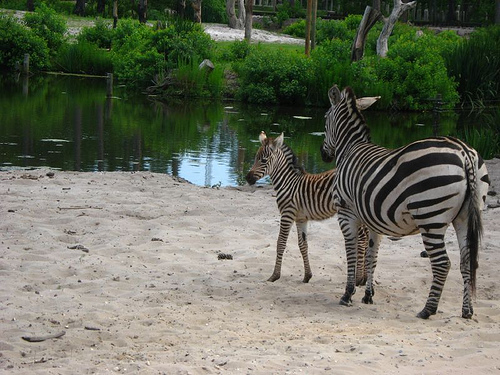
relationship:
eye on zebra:
[321, 115, 330, 124] [319, 82, 490, 322]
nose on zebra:
[318, 146, 329, 159] [319, 82, 490, 322]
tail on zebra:
[463, 152, 483, 298] [319, 82, 490, 322]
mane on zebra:
[340, 87, 374, 150] [319, 82, 490, 322]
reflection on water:
[177, 124, 252, 193] [4, 67, 499, 186]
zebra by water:
[319, 82, 490, 322] [4, 67, 499, 186]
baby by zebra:
[241, 125, 380, 290] [319, 82, 490, 322]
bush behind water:
[111, 16, 179, 89] [4, 67, 499, 186]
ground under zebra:
[3, 173, 499, 373] [319, 82, 490, 322]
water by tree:
[4, 67, 499, 186] [215, 2, 257, 30]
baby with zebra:
[241, 125, 380, 290] [319, 82, 490, 322]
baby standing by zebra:
[241, 125, 380, 290] [319, 82, 490, 322]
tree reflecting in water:
[215, 2, 257, 30] [4, 67, 499, 186]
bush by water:
[111, 16, 179, 89] [4, 67, 499, 186]